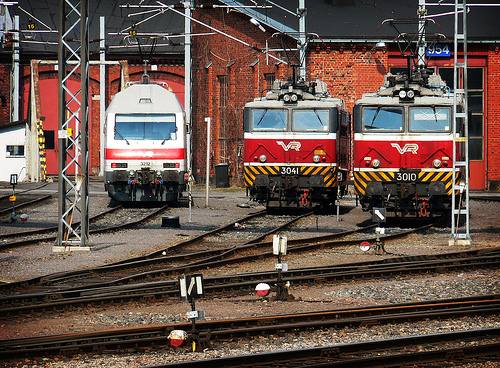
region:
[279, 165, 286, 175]
white number on train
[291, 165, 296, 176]
white number on train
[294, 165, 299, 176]
white number on train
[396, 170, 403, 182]
white number on train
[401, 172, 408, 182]
white number on train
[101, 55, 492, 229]
Trains parked in the rail yard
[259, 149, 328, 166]
head lights on the train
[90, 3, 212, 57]
electric wires above the train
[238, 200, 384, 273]
tracks on the ground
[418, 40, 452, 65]
Numbers 954 on the wall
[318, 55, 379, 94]
brick wall behind the train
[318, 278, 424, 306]
gravel in between the tracks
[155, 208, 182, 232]
box on the ground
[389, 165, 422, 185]
Number 3010 on the train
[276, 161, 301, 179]
number 3041 on the train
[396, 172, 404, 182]
white number on train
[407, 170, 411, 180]
white number on train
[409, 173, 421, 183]
white number on train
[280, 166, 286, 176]
white number on train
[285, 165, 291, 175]
white number on train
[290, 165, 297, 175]
white number on train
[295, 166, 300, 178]
white number on train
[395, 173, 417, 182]
white numbers on train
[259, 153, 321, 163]
headlights on front of train car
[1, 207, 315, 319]
train car on train tracks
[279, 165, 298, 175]
white numbers on front of train car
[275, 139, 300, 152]
white letters on front of train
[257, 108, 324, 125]
windshield wipers on train car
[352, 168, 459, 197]
black and yellow stripes on train car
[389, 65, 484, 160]
windows in the red brick building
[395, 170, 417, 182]
white numbers on front of train car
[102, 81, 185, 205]
red and white train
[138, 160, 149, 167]
black numbers on the train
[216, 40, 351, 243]
this is a train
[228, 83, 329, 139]
front windows on train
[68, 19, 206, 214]
this is a service train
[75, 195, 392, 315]
train tracks split up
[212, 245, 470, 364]
gravel on the tracks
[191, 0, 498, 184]
red brick building in background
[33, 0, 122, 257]
a grey metal post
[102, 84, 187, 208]
A red and white train sitting idle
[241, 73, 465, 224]
A pair of red and white trains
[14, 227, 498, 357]
Several railroad tracks with signals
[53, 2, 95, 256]
Metal pole holding electrical wires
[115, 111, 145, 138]
window on front of train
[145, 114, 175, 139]
window on front of train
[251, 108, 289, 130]
window on front of train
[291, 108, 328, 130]
window on front of train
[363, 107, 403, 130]
window on front of train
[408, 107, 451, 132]
window on front of train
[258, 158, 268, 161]
headlight in front of train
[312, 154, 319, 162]
headlight in front of train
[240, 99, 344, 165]
red and white front of train engine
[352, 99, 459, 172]
red and white front of train engine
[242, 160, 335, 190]
yellow and black safety frame on train engine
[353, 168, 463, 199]
yellow and black safety frame on train engine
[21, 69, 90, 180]
red door on a brick building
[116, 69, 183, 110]
red door on a brick building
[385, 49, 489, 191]
red door on a brick building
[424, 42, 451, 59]
blue sign with white numbers over red door